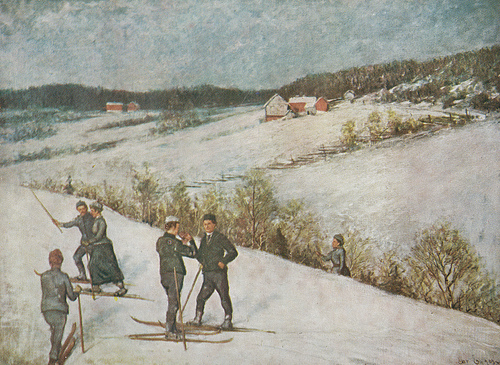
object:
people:
[78, 199, 128, 297]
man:
[177, 212, 239, 330]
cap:
[202, 212, 217, 220]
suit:
[193, 227, 240, 274]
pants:
[194, 265, 234, 315]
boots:
[185, 308, 205, 327]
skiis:
[129, 336, 235, 344]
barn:
[288, 94, 317, 108]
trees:
[404, 224, 489, 310]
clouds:
[153, 20, 222, 65]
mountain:
[332, 47, 500, 109]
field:
[288, 121, 465, 232]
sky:
[87, 27, 306, 67]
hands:
[217, 260, 225, 270]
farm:
[200, 86, 261, 134]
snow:
[335, 165, 395, 196]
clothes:
[87, 215, 113, 246]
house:
[125, 100, 141, 114]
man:
[51, 199, 96, 281]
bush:
[370, 249, 416, 298]